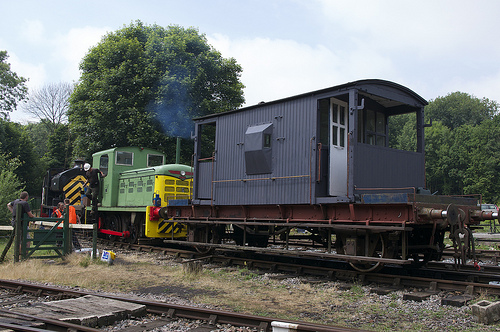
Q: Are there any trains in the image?
A: Yes, there is a train.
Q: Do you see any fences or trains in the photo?
A: Yes, there is a train.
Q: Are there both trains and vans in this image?
A: No, there is a train but no vans.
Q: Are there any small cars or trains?
A: Yes, there is a small train.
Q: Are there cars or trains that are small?
A: Yes, the train is small.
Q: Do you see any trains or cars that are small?
A: Yes, the train is small.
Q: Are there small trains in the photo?
A: Yes, there is a small train.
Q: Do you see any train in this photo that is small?
A: Yes, there is a train that is small.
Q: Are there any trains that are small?
A: Yes, there is a train that is small.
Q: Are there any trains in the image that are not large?
A: Yes, there is a small train.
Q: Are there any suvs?
A: No, there are no suvs.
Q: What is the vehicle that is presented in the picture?
A: The vehicle is a train.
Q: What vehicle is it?
A: The vehicle is a train.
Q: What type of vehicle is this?
A: This is a train.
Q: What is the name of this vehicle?
A: This is a train.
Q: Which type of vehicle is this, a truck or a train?
A: This is a train.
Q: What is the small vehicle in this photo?
A: The vehicle is a train.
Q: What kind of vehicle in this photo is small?
A: The vehicle is a train.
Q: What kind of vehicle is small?
A: The vehicle is a train.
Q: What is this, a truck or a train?
A: This is a train.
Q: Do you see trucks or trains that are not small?
A: No, there is a train but it is small.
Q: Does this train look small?
A: Yes, the train is small.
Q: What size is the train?
A: The train is small.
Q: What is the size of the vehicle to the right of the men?
A: The train is small.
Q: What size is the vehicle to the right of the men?
A: The train is small.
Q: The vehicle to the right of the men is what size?
A: The train is small.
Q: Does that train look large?
A: No, the train is small.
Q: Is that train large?
A: No, the train is small.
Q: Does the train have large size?
A: No, the train is small.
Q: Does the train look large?
A: No, the train is small.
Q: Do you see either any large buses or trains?
A: No, there is a train but it is small.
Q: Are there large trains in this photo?
A: No, there is a train but it is small.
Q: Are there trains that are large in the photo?
A: No, there is a train but it is small.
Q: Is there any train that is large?
A: No, there is a train but it is small.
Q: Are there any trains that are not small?
A: No, there is a train but it is small.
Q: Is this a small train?
A: Yes, this is a small train.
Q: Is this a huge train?
A: No, this is a small train.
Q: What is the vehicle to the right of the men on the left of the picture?
A: The vehicle is a train.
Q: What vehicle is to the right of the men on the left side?
A: The vehicle is a train.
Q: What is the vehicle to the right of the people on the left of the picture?
A: The vehicle is a train.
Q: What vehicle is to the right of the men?
A: The vehicle is a train.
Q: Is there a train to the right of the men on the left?
A: Yes, there is a train to the right of the men.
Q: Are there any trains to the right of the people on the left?
A: Yes, there is a train to the right of the men.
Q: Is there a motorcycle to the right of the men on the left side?
A: No, there is a train to the right of the men.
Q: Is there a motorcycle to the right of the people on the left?
A: No, there is a train to the right of the men.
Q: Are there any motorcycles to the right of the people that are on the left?
A: No, there is a train to the right of the men.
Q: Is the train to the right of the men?
A: Yes, the train is to the right of the men.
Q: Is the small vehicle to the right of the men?
A: Yes, the train is to the right of the men.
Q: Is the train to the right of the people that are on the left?
A: Yes, the train is to the right of the men.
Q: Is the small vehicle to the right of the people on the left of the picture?
A: Yes, the train is to the right of the men.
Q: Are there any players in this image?
A: No, there are no players.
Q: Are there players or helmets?
A: No, there are no players or helmets.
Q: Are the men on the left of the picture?
A: Yes, the men are on the left of the image.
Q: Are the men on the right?
A: No, the men are on the left of the image.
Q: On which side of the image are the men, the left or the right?
A: The men are on the left of the image.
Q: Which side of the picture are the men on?
A: The men are on the left of the image.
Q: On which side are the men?
A: The men are on the left of the image.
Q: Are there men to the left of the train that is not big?
A: Yes, there are men to the left of the train.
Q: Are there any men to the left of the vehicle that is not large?
A: Yes, there are men to the left of the train.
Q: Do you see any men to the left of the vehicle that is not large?
A: Yes, there are men to the left of the train.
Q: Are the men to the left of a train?
A: Yes, the men are to the left of a train.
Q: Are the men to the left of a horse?
A: No, the men are to the left of a train.